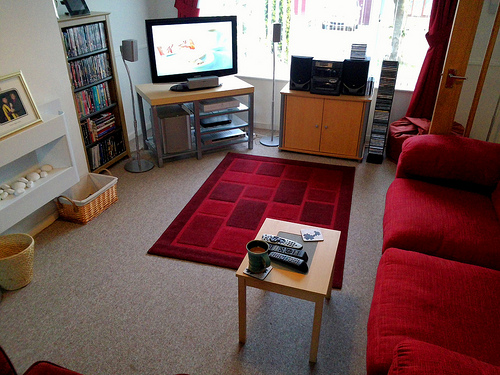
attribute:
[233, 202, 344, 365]
table — small, wooden, cluttered, light brown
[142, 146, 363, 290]
rug — red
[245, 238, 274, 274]
coffee — brown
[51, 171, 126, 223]
basket — small, brown, wicker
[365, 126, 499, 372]
couch — red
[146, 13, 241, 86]
television — on, black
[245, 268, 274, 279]
coaster — white, blue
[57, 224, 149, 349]
floor — grey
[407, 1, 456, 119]
curtain — pulled back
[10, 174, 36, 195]
rocks — white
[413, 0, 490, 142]
door — open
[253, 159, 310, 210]
patterns — rectangular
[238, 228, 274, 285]
mug — green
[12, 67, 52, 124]
frame — golden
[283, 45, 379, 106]
stereo — black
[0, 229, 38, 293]
basket — round